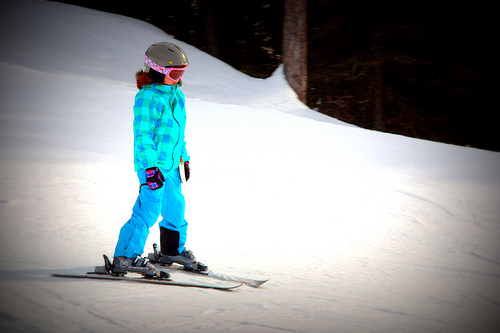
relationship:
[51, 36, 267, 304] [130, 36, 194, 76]
girl wearing helmet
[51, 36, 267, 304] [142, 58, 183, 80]
girl wearing goggles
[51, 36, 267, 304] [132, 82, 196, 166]
girl wearing jacket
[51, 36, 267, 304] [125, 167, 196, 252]
girl wearing pants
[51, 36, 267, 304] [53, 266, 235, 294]
girl wearing ski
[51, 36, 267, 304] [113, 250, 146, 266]
girl wearing boot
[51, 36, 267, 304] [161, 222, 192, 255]
girl wearing boot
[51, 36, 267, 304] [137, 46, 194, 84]
girl has head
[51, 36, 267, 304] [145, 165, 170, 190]
girl wearing glove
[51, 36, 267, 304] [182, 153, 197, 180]
girl wearing glove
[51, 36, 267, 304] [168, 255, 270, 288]
girl wearing ski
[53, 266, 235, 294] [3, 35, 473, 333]
ski on snow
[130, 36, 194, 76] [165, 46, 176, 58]
helmet has hole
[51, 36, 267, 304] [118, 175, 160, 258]
girl has leg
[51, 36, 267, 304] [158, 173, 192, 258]
girl has leg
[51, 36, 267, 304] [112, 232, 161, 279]
girl has foot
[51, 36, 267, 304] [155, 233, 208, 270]
girl has foot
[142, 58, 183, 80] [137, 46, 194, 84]
goggles are on head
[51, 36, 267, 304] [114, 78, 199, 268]
girl has body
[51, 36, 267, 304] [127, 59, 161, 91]
girl has hair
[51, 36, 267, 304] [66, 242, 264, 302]
girl standing on skis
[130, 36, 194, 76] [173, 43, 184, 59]
helmet has hole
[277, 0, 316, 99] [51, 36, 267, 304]
tree left of girl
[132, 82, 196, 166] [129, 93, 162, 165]
jacket has sleeve